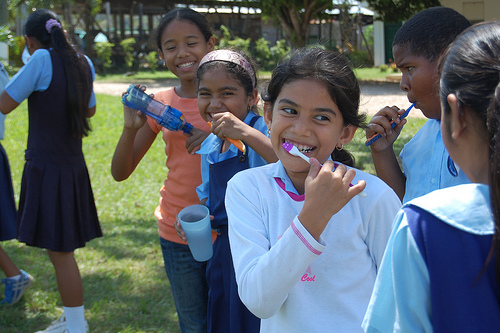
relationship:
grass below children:
[94, 214, 154, 328] [111, 8, 496, 331]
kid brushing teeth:
[247, 55, 389, 281] [289, 142, 315, 168]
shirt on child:
[142, 87, 211, 242] [111, 6, 216, 329]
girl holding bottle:
[121, 14, 213, 312] [123, 88, 195, 138]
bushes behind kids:
[107, 19, 242, 56] [116, 9, 482, 290]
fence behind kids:
[91, 2, 376, 65] [99, 5, 498, 331]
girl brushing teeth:
[248, 55, 393, 326] [267, 123, 325, 166]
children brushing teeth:
[111, 0, 497, 332] [287, 139, 309, 154]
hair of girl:
[20, 5, 95, 142] [3, 11, 94, 327]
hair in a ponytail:
[20, 5, 95, 142] [39, 14, 94, 144]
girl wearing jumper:
[3, 11, 94, 327] [12, 44, 107, 251]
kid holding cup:
[181, 48, 281, 331] [173, 185, 223, 260]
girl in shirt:
[121, 14, 213, 312] [135, 80, 210, 232]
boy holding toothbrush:
[366, 7, 473, 206] [363, 100, 416, 144]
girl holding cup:
[166, 60, 293, 329] [176, 204, 216, 264]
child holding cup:
[172, 46, 279, 331] [176, 204, 216, 264]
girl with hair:
[3, 11, 94, 327] [53, 45, 85, 100]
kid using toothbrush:
[236, 55, 388, 325] [280, 137, 312, 162]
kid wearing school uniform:
[0, 3, 98, 331] [3, 49, 101, 254]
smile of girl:
[173, 59, 199, 71] [110, 5, 243, 332]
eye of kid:
[312, 111, 333, 124] [110, 37, 350, 325]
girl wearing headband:
[166, 60, 293, 329] [189, 42, 274, 80]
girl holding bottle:
[121, 14, 213, 312] [121, 86, 192, 134]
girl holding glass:
[166, 60, 293, 329] [171, 197, 216, 266]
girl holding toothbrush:
[166, 60, 293, 329] [202, 105, 249, 153]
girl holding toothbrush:
[361, 17, 497, 329] [363, 100, 416, 144]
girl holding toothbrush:
[248, 55, 393, 326] [277, 135, 341, 183]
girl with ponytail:
[3, 11, 94, 327] [45, 17, 94, 141]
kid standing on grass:
[236, 55, 388, 325] [1, 92, 497, 331]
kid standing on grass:
[0, 3, 98, 331] [1, 92, 497, 331]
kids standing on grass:
[111, 11, 207, 331] [1, 92, 497, 331]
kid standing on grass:
[181, 48, 281, 331] [1, 92, 497, 331]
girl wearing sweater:
[248, 55, 393, 326] [231, 172, 401, 326]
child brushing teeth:
[218, 30, 418, 333] [277, 135, 317, 160]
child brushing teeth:
[218, 30, 418, 333] [308, 142, 314, 151]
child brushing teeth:
[218, 30, 418, 333] [303, 142, 308, 152]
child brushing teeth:
[218, 30, 418, 333] [297, 142, 303, 150]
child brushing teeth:
[218, 30, 418, 333] [291, 139, 300, 151]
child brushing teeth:
[0, 7, 105, 331] [283, 137, 315, 152]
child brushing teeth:
[218, 30, 418, 333] [286, 139, 313, 153]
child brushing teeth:
[218, 30, 418, 333] [275, 131, 316, 158]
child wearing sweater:
[218, 30, 418, 312] [148, 150, 403, 323]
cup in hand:
[180, 204, 214, 263] [175, 211, 214, 242]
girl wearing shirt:
[248, 55, 393, 326] [223, 159, 400, 329]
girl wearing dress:
[3, 11, 94, 327] [12, 49, 106, 254]